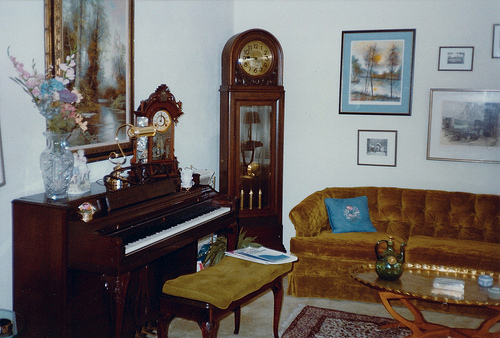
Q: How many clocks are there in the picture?
A: Two.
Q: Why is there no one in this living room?
A: People are too busy.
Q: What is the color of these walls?
A: White.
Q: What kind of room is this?
A: A living room.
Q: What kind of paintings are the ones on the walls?
A: Paintings of nature.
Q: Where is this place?
A: Inside someone's home.